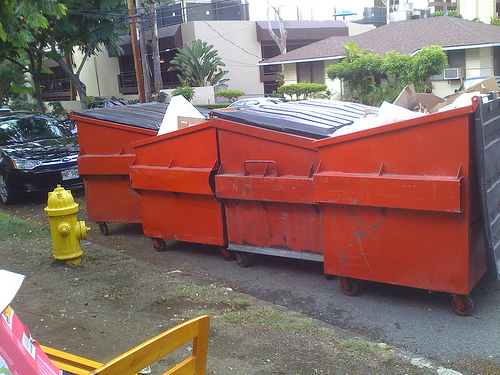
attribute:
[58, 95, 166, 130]
fire lid — closed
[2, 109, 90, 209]
car — black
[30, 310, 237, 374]
chair — brown 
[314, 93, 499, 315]
bins — red, black 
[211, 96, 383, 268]
bins — red, black 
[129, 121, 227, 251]
bins — red, black 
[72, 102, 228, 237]
bins — red, black 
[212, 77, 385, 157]
lid — black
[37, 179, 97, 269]
fire hydrant — yellow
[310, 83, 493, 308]
trash can — red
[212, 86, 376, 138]
cover — black 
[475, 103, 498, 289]
lid — open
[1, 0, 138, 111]
tree — green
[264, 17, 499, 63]
roof — brown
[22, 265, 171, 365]
ground — brown 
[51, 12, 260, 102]
building — apartment